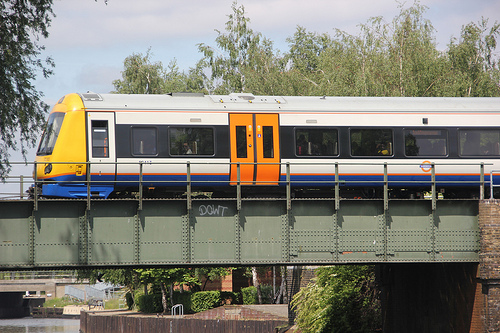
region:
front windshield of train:
[30, 102, 74, 158]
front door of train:
[83, 108, 118, 183]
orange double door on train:
[224, 111, 278, 192]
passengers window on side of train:
[168, 120, 217, 160]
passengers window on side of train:
[292, 120, 342, 162]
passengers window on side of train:
[346, 124, 397, 159]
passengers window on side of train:
[402, 123, 449, 160]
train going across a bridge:
[10, 59, 498, 326]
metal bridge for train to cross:
[10, 168, 498, 294]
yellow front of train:
[7, 70, 111, 203]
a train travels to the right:
[8, 79, 495, 214]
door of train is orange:
[217, 103, 285, 188]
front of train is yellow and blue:
[24, 94, 94, 201]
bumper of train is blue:
[21, 172, 73, 197]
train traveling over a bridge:
[0, 81, 499, 303]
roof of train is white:
[82, 85, 499, 130]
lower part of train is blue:
[46, 163, 497, 203]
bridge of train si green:
[0, 169, 499, 284]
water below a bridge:
[5, 195, 121, 332]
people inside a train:
[338, 130, 411, 157]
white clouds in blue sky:
[61, 7, 120, 38]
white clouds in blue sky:
[68, 43, 108, 88]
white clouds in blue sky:
[146, 7, 201, 49]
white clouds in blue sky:
[259, 5, 310, 23]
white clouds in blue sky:
[426, 8, 453, 30]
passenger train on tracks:
[35, 90, 485, 205]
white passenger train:
[35, 90, 475, 182]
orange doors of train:
[216, 95, 286, 200]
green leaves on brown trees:
[286, 56, 359, 79]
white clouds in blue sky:
[11, 146, 36, 177]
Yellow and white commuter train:
[35, 79, 498, 213]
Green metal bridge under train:
[15, 175, 492, 322]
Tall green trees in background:
[123, 0, 495, 102]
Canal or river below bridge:
[19, 284, 113, 331]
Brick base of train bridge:
[470, 191, 495, 331]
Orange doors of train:
[228, 109, 285, 184]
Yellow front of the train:
[28, 80, 106, 191]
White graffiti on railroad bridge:
[191, 202, 233, 234]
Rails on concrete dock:
[165, 288, 186, 324]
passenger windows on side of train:
[282, 125, 496, 166]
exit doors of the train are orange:
[225, 110, 283, 188]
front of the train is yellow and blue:
[30, 88, 89, 206]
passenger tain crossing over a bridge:
[32, 90, 499, 202]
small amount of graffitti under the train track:
[194, 201, 228, 218]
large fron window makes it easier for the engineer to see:
[31, 111, 66, 157]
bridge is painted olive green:
[2, 204, 479, 263]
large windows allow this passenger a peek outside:
[169, 128, 211, 157]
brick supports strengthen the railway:
[476, 185, 498, 328]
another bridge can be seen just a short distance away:
[5, 274, 80, 331]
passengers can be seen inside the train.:
[300, 131, 491, 155]